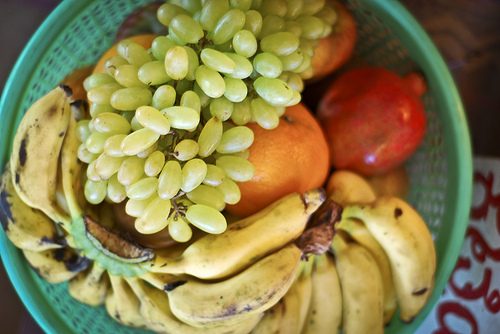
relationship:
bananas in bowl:
[153, 188, 438, 334] [2, 2, 475, 333]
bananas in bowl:
[2, 84, 326, 333] [2, 2, 475, 333]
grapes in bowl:
[69, 2, 337, 245] [2, 2, 475, 333]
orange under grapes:
[315, 1, 358, 79] [69, 2, 337, 245]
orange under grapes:
[227, 106, 330, 221] [69, 2, 337, 245]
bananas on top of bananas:
[2, 84, 326, 333] [153, 188, 438, 334]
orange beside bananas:
[227, 106, 330, 221] [153, 188, 438, 334]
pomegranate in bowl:
[316, 68, 430, 176] [2, 2, 475, 333]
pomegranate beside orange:
[316, 68, 430, 176] [227, 106, 330, 221]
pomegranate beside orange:
[316, 68, 430, 176] [315, 1, 358, 79]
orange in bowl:
[315, 1, 358, 79] [2, 2, 475, 333]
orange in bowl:
[227, 106, 330, 221] [2, 2, 475, 333]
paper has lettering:
[411, 155, 499, 333] [431, 170, 499, 334]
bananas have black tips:
[153, 188, 438, 334] [56, 82, 83, 113]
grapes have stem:
[69, 2, 337, 245] [168, 195, 188, 223]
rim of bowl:
[0, 1, 92, 169] [2, 2, 475, 333]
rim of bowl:
[375, 1, 475, 334] [2, 2, 475, 333]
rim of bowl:
[0, 229, 73, 333] [2, 2, 475, 333]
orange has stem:
[227, 106, 330, 221] [278, 114, 298, 127]